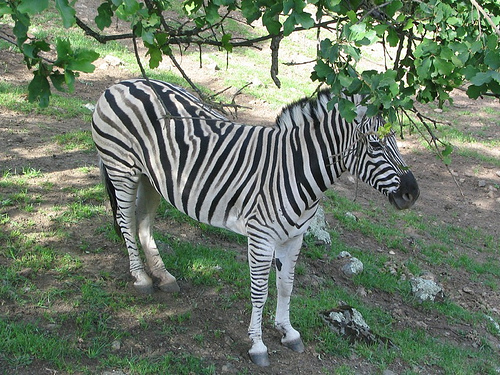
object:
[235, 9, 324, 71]
tree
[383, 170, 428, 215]
nose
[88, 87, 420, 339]
zebra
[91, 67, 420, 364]
zebra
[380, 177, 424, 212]
nostril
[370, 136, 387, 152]
eye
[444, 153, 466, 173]
ground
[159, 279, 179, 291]
back left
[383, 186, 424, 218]
nose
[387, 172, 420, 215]
mouth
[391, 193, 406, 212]
mouth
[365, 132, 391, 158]
eye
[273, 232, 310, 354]
front leg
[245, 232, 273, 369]
front leg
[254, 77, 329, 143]
spikey mane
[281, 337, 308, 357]
hoof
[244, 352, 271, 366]
hoof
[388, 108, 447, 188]
ground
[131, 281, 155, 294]
hoof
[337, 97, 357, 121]
leaf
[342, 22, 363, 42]
leaf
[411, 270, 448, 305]
rock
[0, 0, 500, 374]
ground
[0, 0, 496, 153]
sign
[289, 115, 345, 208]
neck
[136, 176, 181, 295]
rear leg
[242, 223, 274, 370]
leg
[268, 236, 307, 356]
leg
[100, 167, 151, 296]
leg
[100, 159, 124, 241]
tail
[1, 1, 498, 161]
leaves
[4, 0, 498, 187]
tree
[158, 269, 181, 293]
hoof